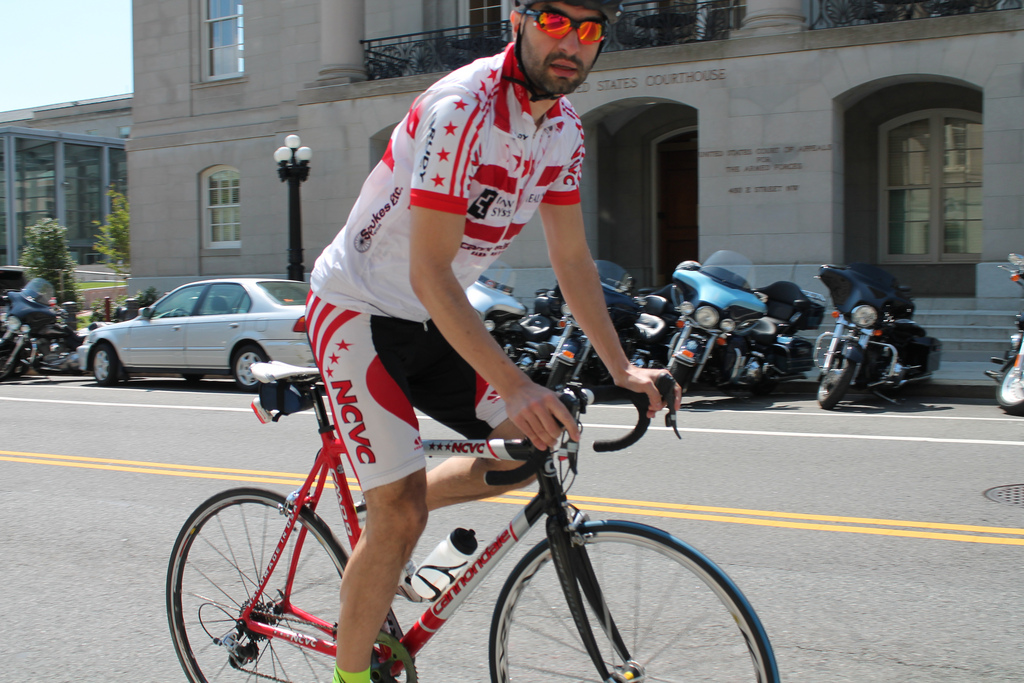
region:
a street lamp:
[272, 138, 310, 271]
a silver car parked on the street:
[78, 287, 338, 414]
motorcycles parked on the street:
[471, 260, 889, 407]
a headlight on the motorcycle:
[689, 309, 718, 328]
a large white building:
[125, 12, 988, 306]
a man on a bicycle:
[212, 23, 775, 679]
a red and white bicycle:
[179, 358, 715, 679]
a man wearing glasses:
[319, 9, 687, 651]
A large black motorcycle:
[811, 265, 939, 405]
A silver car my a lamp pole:
[78, 265, 307, 374]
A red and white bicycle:
[163, 364, 778, 679]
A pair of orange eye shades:
[529, 7, 607, 47]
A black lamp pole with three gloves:
[269, 132, 320, 278]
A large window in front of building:
[845, 76, 991, 285]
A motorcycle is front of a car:
[5, 268, 63, 392]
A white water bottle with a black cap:
[403, 522, 481, 598]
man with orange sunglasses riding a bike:
[169, 2, 777, 674]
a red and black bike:
[163, 358, 773, 679]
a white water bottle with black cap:
[409, 520, 482, 601]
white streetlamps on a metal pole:
[273, 134, 312, 278]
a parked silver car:
[83, 274, 319, 386]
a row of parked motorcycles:
[501, 251, 1021, 411]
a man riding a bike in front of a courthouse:
[131, 4, 1021, 676]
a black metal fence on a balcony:
[359, 0, 733, 83]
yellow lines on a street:
[1, 375, 1016, 679]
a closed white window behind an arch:
[830, 72, 982, 297]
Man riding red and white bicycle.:
[165, 6, 772, 677]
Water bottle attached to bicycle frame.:
[401, 523, 482, 623]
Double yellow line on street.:
[595, 486, 1020, 566]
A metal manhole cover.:
[980, 470, 1020, 516]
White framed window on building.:
[196, 163, 251, 259]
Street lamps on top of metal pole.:
[270, 128, 313, 281]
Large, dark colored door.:
[643, 100, 700, 294]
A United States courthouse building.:
[124, 8, 1019, 370]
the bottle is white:
[424, 540, 457, 597]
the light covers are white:
[271, 127, 320, 182]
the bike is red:
[290, 443, 367, 524]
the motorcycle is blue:
[701, 276, 737, 305]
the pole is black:
[280, 190, 312, 230]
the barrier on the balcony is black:
[379, 18, 468, 80]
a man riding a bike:
[163, 0, 784, 680]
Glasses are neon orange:
[512, 6, 602, 44]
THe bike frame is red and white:
[237, 360, 583, 678]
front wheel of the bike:
[490, 518, 785, 680]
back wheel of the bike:
[166, 484, 360, 680]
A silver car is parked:
[73, 274, 318, 386]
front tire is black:
[85, 339, 115, 382]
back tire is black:
[231, 338, 261, 383]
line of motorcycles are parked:
[512, 253, 1021, 409]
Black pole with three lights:
[272, 132, 310, 275]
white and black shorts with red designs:
[303, 262, 556, 491]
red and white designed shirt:
[307, 40, 584, 328]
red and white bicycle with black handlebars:
[167, 350, 794, 679]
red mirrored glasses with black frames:
[509, 6, 611, 49]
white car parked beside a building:
[78, 277, 334, 392]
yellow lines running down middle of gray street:
[3, 442, 1022, 550]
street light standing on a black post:
[274, 129, 314, 286]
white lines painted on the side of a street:
[3, 393, 1022, 452]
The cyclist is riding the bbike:
[299, 3, 680, 680]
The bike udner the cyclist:
[171, 352, 779, 681]